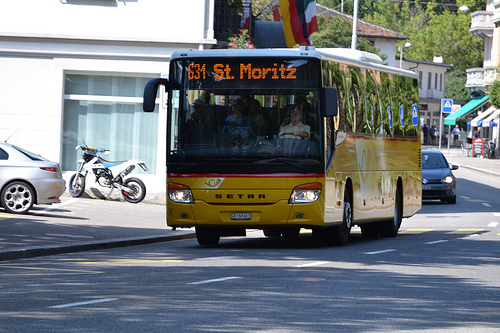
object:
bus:
[139, 40, 430, 251]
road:
[0, 147, 498, 332]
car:
[421, 145, 461, 209]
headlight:
[441, 173, 456, 188]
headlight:
[282, 183, 322, 209]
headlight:
[162, 182, 197, 211]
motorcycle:
[67, 137, 151, 206]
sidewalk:
[66, 177, 167, 211]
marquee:
[165, 53, 326, 94]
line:
[41, 190, 500, 324]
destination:
[181, 60, 299, 85]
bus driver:
[277, 104, 314, 144]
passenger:
[223, 98, 251, 126]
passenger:
[244, 97, 268, 134]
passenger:
[188, 96, 211, 128]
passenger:
[289, 93, 315, 113]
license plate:
[224, 207, 255, 224]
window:
[54, 66, 164, 181]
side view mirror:
[318, 82, 344, 124]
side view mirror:
[136, 73, 169, 119]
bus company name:
[209, 189, 269, 208]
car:
[0, 134, 69, 220]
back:
[15, 143, 70, 214]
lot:
[0, 190, 82, 225]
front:
[138, 46, 359, 251]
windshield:
[168, 87, 325, 175]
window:
[336, 84, 369, 135]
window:
[364, 89, 391, 139]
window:
[398, 97, 421, 136]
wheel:
[338, 188, 359, 241]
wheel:
[387, 172, 407, 233]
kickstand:
[103, 184, 118, 201]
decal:
[196, 174, 229, 192]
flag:
[250, 1, 312, 49]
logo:
[210, 191, 272, 207]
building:
[1, 0, 256, 196]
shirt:
[274, 121, 314, 143]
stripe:
[165, 134, 424, 180]